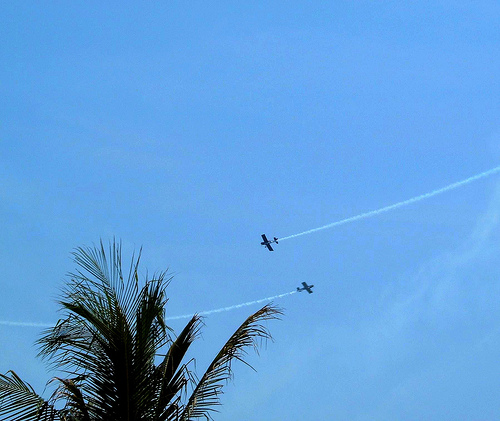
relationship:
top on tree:
[0, 254, 283, 420] [0, 233, 283, 419]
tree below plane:
[0, 254, 283, 420] [254, 228, 318, 300]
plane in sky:
[260, 231, 279, 254] [2, 0, 500, 420]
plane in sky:
[297, 280, 315, 295] [2, 0, 500, 420]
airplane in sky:
[260, 231, 279, 254] [2, 0, 500, 420]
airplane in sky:
[297, 280, 315, 295] [2, 0, 500, 420]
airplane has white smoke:
[260, 231, 279, 254] [279, 164, 498, 243]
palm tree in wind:
[0, 254, 283, 420] [1, 1, 499, 420]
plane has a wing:
[260, 231, 279, 254] [262, 232, 268, 242]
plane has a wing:
[297, 280, 315, 295] [301, 279, 309, 289]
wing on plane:
[262, 232, 268, 242] [260, 231, 279, 254]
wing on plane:
[301, 279, 309, 289] [297, 280, 315, 295]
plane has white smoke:
[260, 231, 279, 254] [279, 164, 498, 243]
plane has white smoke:
[297, 280, 315, 295] [170, 288, 295, 321]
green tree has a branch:
[0, 254, 283, 420] [202, 301, 283, 419]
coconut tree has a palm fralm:
[0, 254, 283, 420] [202, 301, 283, 419]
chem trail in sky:
[279, 164, 498, 243] [2, 0, 500, 420]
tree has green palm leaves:
[0, 254, 283, 420] [202, 301, 283, 419]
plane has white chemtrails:
[260, 231, 279, 254] [279, 164, 498, 243]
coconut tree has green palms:
[0, 254, 283, 420] [1, 369, 58, 420]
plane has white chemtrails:
[297, 280, 315, 295] [170, 288, 295, 321]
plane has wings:
[260, 231, 279, 254] [265, 243, 273, 251]